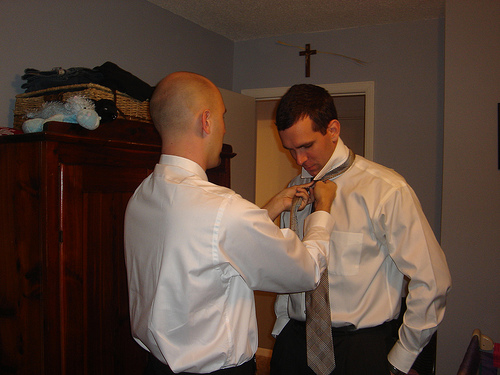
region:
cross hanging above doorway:
[296, 40, 318, 76]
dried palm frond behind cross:
[272, 38, 371, 68]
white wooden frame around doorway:
[236, 81, 377, 168]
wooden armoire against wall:
[0, 118, 233, 373]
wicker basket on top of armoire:
[13, 83, 155, 123]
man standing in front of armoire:
[122, 68, 337, 374]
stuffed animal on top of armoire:
[18, 93, 101, 133]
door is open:
[214, 85, 258, 204]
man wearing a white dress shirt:
[121, 153, 331, 373]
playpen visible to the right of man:
[446, 329, 498, 371]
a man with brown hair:
[247, 98, 429, 350]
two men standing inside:
[142, 44, 497, 337]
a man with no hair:
[137, 73, 295, 193]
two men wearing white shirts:
[144, 88, 441, 352]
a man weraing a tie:
[272, 116, 436, 368]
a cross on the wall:
[282, 37, 339, 72]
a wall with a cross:
[287, 37, 331, 78]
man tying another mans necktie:
[278, 168, 353, 371]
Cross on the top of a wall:
[296, 40, 320, 78]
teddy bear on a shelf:
[22, 88, 94, 144]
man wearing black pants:
[262, 305, 382, 370]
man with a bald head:
[145, 79, 225, 151]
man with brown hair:
[275, 78, 343, 151]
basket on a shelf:
[6, 65, 153, 125]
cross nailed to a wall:
[286, 38, 323, 67]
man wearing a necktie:
[276, 172, 344, 373]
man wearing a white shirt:
[126, 158, 271, 363]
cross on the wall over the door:
[296, 39, 318, 81]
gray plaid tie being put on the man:
[286, 143, 358, 374]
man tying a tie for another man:
[123, 75, 335, 367]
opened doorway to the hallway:
[214, 77, 376, 205]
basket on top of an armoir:
[28, 78, 157, 124]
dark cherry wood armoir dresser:
[0, 125, 235, 370]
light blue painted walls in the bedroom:
[225, 5, 498, 373]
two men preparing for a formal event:
[122, 70, 449, 372]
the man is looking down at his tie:
[269, 82, 449, 374]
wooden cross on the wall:
[295, 41, 317, 80]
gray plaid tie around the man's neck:
[295, 151, 354, 374]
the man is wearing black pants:
[272, 315, 406, 374]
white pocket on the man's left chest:
[325, 229, 362, 274]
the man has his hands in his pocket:
[270, 311, 440, 374]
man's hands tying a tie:
[278, 173, 334, 208]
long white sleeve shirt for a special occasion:
[126, 154, 327, 363]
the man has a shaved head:
[155, 69, 226, 171]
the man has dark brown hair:
[276, 79, 338, 132]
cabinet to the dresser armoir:
[60, 158, 152, 372]